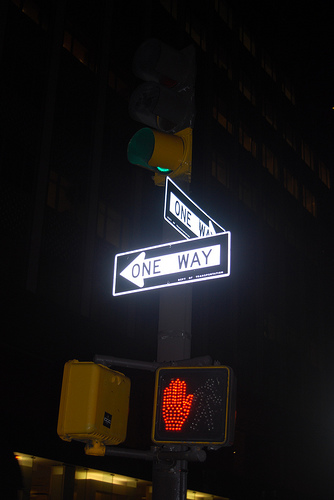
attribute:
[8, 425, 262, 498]
frame — black 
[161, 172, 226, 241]
sign — glowing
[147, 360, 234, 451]
sign — pedestrian crossing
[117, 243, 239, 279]
arrow — white 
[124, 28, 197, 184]
light — green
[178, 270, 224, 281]
writing — small 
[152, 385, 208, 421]
hand — orange 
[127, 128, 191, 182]
light — green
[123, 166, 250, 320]
sign — cross walk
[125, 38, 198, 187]
traffic signal — yellow 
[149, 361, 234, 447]
signal — red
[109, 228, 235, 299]
sign — white, black, glowing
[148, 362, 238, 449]
light — pedestrian